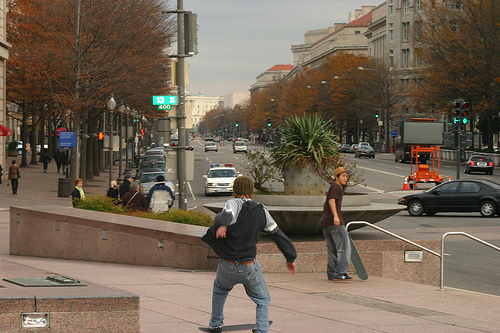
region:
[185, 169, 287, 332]
A kid on a skate board.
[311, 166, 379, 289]
A young man with a skate board.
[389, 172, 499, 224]
a black sedan making a turn.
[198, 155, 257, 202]
A police car driving down the road.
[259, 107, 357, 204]
An odd looking bush in the middle of the city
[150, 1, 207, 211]
A street lamp with a street sign attached.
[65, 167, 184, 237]
A small group of people gathered at the curb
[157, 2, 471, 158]
tall buildings line the street.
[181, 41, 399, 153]
Trees line the busy city street.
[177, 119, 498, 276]
A busy street in the city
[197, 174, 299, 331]
man staggering on sidewalk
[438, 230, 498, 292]
metal stair guardrail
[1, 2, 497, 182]
trees showing autumn leaves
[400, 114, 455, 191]
construction caution sign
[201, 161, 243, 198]
police vehicle with headlamps lit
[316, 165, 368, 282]
young man holding skateboard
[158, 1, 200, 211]
road traffic light on pole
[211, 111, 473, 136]
long row of green traffic lights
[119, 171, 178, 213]
two people sitting on planter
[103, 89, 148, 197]
row of street side lights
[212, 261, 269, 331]
a pair of baggy blue jeans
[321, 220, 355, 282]
a pair of baggy blue jeans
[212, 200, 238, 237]
an arm of a skater boy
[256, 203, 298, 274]
an arm of a skater boy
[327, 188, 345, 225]
an arm of a skater boy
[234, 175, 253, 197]
the brown hair of a skater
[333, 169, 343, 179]
the brown hair of a skater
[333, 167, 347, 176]
the tan hat of the skater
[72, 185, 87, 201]
a bright green scarf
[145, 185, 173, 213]
a black and white jacket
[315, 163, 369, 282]
young man is holding skateboard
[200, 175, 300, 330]
kid with hat is skateboarding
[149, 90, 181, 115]
green street signs on a pole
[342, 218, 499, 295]
two silver hand railings on stairs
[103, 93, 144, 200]
line of street lights on sidewalk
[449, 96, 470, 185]
stoplight has green go light on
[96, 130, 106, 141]
orange do not walk symbol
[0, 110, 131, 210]
people walking down tree lined sidewalk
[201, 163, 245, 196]
police car on the road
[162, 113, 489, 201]
wide roadway with cars on it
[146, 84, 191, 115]
Green street sign on pole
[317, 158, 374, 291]
Boy holding skate board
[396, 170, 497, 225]
Black car on street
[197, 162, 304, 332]
Boy skating on skate board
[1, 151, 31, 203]
Person walking on sidewalk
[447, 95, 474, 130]
Traffic Light turned green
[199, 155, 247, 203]
Police car on street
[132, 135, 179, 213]
Cars parked on street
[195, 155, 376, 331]
Two boys skateboarding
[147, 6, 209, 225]
Traffic pole with green street sign